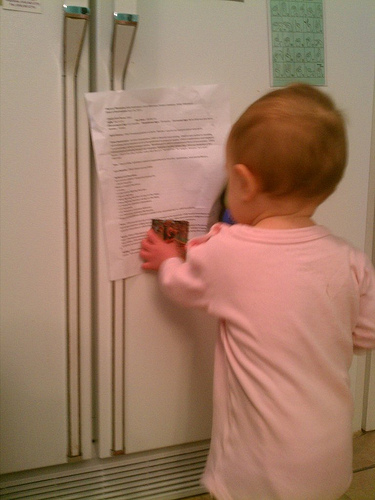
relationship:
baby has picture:
[211, 103, 345, 500] [146, 218, 222, 284]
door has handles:
[57, 15, 129, 173] [46, 35, 98, 134]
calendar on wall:
[250, 12, 356, 68] [14, 116, 53, 261]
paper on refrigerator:
[115, 104, 217, 196] [0, 181, 201, 430]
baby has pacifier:
[211, 103, 345, 500] [201, 178, 260, 219]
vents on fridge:
[69, 454, 136, 491] [83, 32, 207, 470]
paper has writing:
[115, 104, 217, 196] [101, 118, 174, 158]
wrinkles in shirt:
[200, 300, 256, 380] [184, 221, 323, 429]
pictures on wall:
[139, 163, 226, 264] [14, 116, 53, 261]